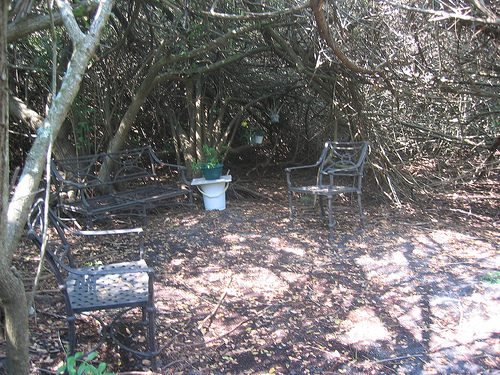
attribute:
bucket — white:
[175, 157, 262, 227]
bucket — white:
[200, 177, 240, 210]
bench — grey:
[65, 122, 215, 222]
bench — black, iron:
[42, 156, 187, 224]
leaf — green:
[35, 124, 52, 140]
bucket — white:
[247, 134, 266, 144]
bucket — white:
[198, 162, 225, 179]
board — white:
[191, 174, 233, 183]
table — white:
[183, 165, 237, 215]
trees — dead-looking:
[2, 3, 486, 203]